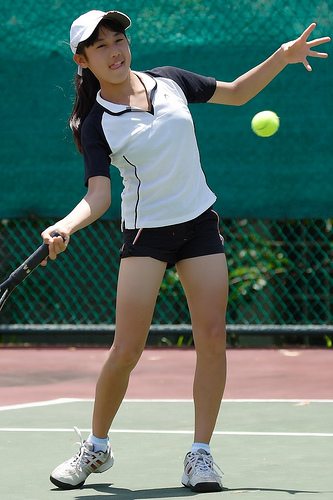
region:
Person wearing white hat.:
[68, 4, 128, 50]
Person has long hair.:
[62, 75, 93, 106]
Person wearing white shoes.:
[57, 443, 247, 492]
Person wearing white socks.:
[77, 434, 230, 470]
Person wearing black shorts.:
[135, 226, 245, 250]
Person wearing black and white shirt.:
[73, 103, 186, 171]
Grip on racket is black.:
[19, 210, 70, 299]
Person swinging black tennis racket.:
[21, 196, 82, 268]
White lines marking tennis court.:
[236, 379, 310, 483]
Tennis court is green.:
[242, 422, 265, 486]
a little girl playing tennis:
[9, 7, 303, 490]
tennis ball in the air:
[229, 97, 310, 174]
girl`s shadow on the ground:
[37, 461, 306, 496]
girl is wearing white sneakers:
[37, 421, 252, 488]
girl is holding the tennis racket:
[4, 215, 85, 281]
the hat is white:
[50, 5, 147, 44]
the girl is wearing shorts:
[88, 190, 243, 270]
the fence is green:
[16, 170, 321, 342]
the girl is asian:
[47, 2, 156, 108]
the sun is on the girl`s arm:
[20, 181, 110, 262]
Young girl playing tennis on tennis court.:
[33, 4, 332, 499]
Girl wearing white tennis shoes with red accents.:
[43, 448, 228, 498]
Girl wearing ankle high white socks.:
[87, 430, 213, 453]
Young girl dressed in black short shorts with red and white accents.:
[110, 208, 243, 268]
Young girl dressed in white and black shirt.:
[80, 64, 227, 230]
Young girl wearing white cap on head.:
[55, 8, 140, 51]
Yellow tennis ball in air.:
[242, 107, 287, 139]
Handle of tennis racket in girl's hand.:
[1, 209, 70, 315]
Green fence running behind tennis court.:
[228, 212, 331, 346]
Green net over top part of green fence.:
[6, 11, 64, 227]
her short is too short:
[120, 236, 226, 264]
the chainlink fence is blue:
[49, 272, 105, 318]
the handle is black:
[15, 237, 54, 283]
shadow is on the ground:
[102, 478, 177, 497]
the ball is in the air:
[250, 105, 284, 134]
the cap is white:
[68, 6, 129, 43]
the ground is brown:
[244, 350, 318, 385]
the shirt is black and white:
[85, 100, 217, 203]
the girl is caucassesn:
[15, 1, 315, 494]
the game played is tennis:
[1, 2, 329, 488]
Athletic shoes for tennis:
[18, 429, 255, 492]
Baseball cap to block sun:
[54, 8, 142, 45]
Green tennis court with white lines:
[225, 401, 317, 472]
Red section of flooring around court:
[32, 346, 96, 391]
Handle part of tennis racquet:
[2, 251, 42, 301]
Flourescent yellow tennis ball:
[243, 107, 288, 149]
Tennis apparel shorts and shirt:
[92, 78, 217, 264]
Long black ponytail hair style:
[69, 61, 83, 141]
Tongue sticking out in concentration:
[96, 54, 155, 83]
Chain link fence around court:
[233, 175, 315, 311]